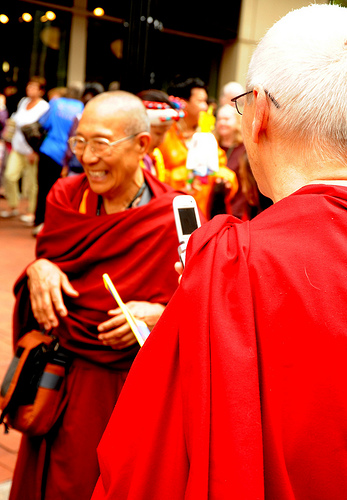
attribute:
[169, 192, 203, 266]
phone — white, flip-phone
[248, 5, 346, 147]
hair — white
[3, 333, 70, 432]
bag — red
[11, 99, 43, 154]
shirt — white, t-shirt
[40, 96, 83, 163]
shirt — blue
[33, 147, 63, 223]
pants — black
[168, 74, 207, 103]
hair — black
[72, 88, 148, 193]
head — bald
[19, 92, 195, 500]
man — laughing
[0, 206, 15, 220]
shoe — white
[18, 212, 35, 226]
shoe — white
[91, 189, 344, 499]
cloak — red, bright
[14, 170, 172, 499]
robe — draped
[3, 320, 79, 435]
bag — orange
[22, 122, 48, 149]
purse — brown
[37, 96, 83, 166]
tshirt — blue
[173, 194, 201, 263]
cell phone — white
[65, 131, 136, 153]
glasses — long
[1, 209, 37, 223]
shoes — white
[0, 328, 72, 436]
bag — orange, black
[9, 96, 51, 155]
t-shirt — white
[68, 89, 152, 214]
skin — brown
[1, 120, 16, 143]
bag — light brown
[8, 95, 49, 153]
shirt — white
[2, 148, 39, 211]
pants — beige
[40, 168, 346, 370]
garments — red, religious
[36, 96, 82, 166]
shirt — light blue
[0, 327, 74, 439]
case — red, black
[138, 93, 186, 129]
head dress — elegant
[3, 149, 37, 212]
pants — Beige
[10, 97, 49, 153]
tshirt — white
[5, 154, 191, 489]
cape — red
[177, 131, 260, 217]
clothes — bright, orange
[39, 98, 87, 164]
shirt — blue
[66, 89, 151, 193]
head — bald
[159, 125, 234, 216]
costume — colorful